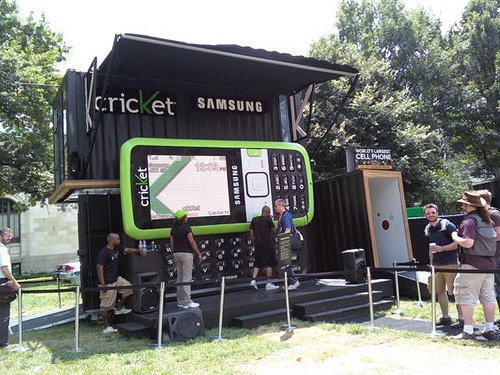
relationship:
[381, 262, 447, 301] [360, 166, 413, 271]
ramp leads to doorway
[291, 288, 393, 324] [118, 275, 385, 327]
steps lead to stage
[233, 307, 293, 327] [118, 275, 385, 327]
steps lead to stage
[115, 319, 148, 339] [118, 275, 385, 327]
steps lead to stage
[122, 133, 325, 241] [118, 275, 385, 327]
sign in front of stage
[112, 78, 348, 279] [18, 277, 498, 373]
black speaker on ground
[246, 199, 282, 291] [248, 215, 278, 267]
man wearing clothes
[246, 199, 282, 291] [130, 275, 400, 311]
man on platform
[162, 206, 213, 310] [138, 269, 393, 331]
woman on platform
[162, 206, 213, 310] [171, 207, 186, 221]
woman wearing bandana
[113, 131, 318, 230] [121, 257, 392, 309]
cellphone on platform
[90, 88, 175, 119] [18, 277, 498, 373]
sign on ground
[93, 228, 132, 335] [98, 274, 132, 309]
man wearing pants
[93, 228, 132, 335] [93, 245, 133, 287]
man wearing shirt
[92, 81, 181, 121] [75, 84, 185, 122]
cricket on sign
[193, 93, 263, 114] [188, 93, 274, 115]
samsung on sign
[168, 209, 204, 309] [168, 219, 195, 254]
woman wearing shirt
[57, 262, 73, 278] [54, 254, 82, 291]
back end of a car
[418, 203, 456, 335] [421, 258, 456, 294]
man wearing shorts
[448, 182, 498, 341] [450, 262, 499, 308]
man wearing shorts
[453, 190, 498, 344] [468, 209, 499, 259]
man has a backpack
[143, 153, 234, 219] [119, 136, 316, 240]
screen on phone